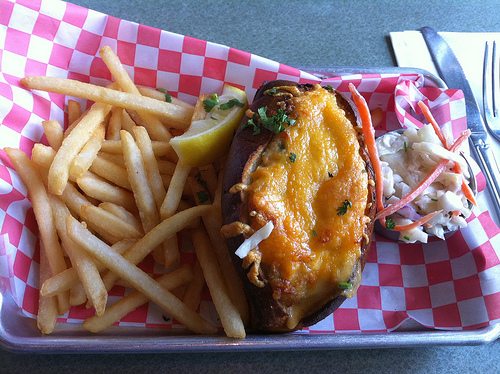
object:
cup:
[365, 128, 477, 244]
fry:
[21, 69, 188, 130]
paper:
[387, 30, 499, 231]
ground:
[60, 0, 500, 69]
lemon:
[165, 85, 251, 166]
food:
[370, 123, 470, 243]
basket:
[1, 65, 500, 356]